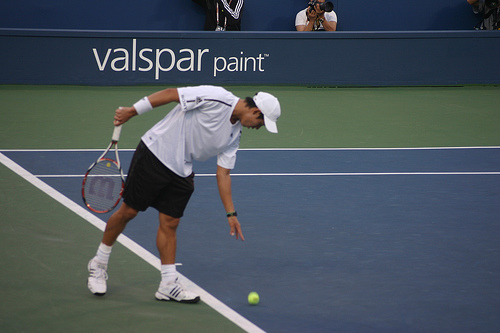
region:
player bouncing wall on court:
[214, 201, 287, 305]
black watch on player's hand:
[212, 204, 256, 223]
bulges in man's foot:
[149, 212, 199, 254]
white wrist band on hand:
[129, 97, 164, 124]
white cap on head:
[249, 87, 304, 152]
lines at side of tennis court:
[309, 155, 377, 197]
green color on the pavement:
[26, 94, 71, 119]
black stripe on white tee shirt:
[179, 91, 238, 119]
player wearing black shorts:
[120, 133, 210, 238]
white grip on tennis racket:
[91, 114, 133, 146]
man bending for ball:
[70, 65, 338, 330]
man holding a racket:
[71, 40, 286, 330]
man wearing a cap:
[30, 58, 322, 315]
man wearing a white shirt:
[60, 60, 290, 328]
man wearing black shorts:
[60, 46, 278, 317]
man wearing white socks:
[45, 48, 272, 328]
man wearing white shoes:
[55, 65, 285, 316]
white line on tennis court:
[286, 165, 407, 183]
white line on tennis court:
[12, 155, 52, 202]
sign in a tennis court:
[81, 29, 307, 86]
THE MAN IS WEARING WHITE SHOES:
[76, 256, 201, 311]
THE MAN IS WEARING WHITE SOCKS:
[88, 235, 179, 285]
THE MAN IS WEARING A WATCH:
[226, 206, 242, 221]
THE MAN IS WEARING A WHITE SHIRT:
[135, 76, 247, 183]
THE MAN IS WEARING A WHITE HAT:
[248, 89, 288, 140]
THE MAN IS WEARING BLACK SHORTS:
[111, 133, 199, 228]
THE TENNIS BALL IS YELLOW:
[242, 288, 263, 307]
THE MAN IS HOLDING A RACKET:
[66, 96, 138, 231]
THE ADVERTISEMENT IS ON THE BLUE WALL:
[84, 26, 278, 88]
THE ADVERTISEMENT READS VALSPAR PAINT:
[77, 32, 280, 91]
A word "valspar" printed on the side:
[92, 27, 210, 87]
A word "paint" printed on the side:
[212, 45, 274, 82]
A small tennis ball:
[241, 277, 269, 310]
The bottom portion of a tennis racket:
[74, 155, 126, 218]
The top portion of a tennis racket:
[102, 124, 124, 156]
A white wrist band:
[128, 89, 158, 116]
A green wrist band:
[217, 203, 245, 226]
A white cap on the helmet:
[255, 85, 288, 135]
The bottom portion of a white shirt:
[142, 107, 197, 174]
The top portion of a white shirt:
[196, 87, 236, 168]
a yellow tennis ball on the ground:
[242, 286, 262, 305]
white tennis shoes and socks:
[80, 248, 200, 306]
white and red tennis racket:
[79, 103, 134, 215]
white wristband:
[132, 96, 157, 112]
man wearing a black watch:
[223, 205, 236, 225]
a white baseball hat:
[250, 90, 282, 132]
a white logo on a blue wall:
[77, 41, 273, 81]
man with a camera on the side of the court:
[291, 0, 342, 30]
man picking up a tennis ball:
[82, 83, 308, 300]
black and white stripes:
[214, 1, 246, 28]